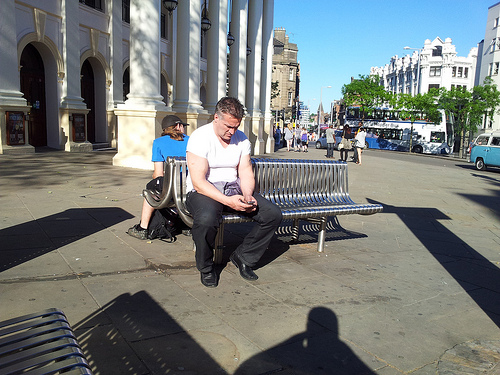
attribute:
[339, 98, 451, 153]
bus — double decker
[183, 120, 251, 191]
shirt — blue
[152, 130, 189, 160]
shirt — blue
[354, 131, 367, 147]
shirt — blue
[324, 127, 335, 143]
shirt — blue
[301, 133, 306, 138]
shirt — blue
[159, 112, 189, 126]
cap — black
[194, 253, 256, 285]
shoes — mens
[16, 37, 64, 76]
arch — entrances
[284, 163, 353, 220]
benches — grey, metal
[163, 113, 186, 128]
hat — black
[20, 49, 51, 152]
wooden door — brown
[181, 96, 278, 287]
man — looking at, sitting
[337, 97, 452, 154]
van — blue, white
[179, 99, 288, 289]
guy — sitting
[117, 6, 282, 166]
pillars — tall, white, stucco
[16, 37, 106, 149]
doorways — arched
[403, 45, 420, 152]
street lamp — tall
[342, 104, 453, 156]
bus — double decker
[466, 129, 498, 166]
volkswagon bus — blue, white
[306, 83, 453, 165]
bus — white, double decker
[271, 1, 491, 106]
sky — clear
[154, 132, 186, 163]
tee shirt — blue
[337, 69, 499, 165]
trees — green